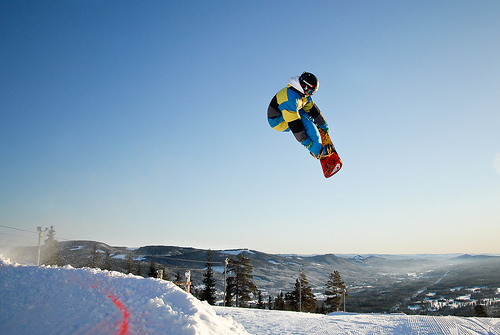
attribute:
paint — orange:
[83, 277, 133, 332]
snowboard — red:
[311, 122, 341, 185]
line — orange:
[84, 279, 137, 331]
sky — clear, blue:
[3, 1, 498, 259]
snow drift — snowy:
[0, 254, 250, 334]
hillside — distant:
[307, 254, 495, 311]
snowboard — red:
[319, 149, 341, 180]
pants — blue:
[256, 68, 391, 187]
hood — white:
[286, 73, 305, 96]